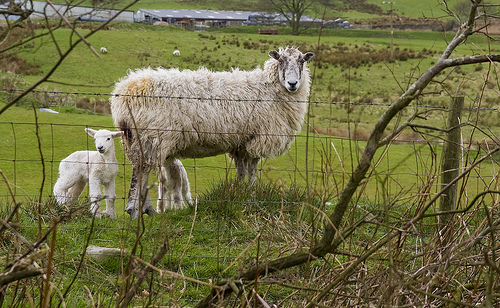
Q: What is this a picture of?
A: Sheep in a field.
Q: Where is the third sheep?
A: Behind the adult sheep.